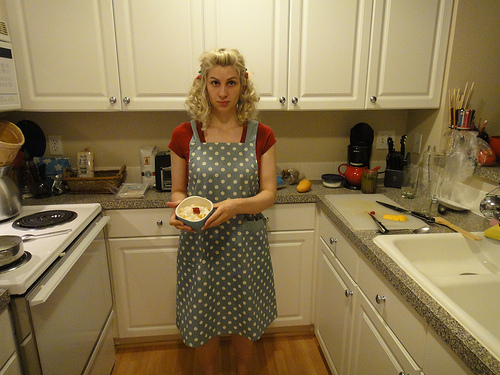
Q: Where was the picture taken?
A: It was taken at the kitchen.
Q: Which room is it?
A: It is a kitchen.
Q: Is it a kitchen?
A: Yes, it is a kitchen.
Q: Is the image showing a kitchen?
A: Yes, it is showing a kitchen.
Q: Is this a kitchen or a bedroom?
A: It is a kitchen.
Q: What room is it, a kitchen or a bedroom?
A: It is a kitchen.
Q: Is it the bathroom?
A: No, it is the kitchen.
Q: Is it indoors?
A: Yes, it is indoors.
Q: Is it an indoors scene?
A: Yes, it is indoors.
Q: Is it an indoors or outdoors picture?
A: It is indoors.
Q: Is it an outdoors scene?
A: No, it is indoors.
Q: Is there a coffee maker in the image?
A: Yes, there is a coffee maker.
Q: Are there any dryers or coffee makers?
A: Yes, there is a coffee maker.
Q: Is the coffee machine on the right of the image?
A: Yes, the coffee machine is on the right of the image.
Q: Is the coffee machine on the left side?
A: No, the coffee machine is on the right of the image.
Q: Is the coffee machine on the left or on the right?
A: The coffee machine is on the right of the image.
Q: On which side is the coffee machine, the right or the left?
A: The coffee machine is on the right of the image.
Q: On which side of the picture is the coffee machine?
A: The coffee machine is on the right of the image.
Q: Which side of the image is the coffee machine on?
A: The coffee machine is on the right of the image.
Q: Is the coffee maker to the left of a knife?
A: Yes, the coffee maker is to the left of a knife.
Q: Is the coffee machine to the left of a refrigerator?
A: No, the coffee machine is to the left of a knife.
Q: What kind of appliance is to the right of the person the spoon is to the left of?
A: The appliance is a coffee maker.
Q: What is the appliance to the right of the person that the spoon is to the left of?
A: The appliance is a coffee maker.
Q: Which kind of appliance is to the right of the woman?
A: The appliance is a coffee maker.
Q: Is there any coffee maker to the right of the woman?
A: Yes, there is a coffee maker to the right of the woman.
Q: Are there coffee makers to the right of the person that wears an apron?
A: Yes, there is a coffee maker to the right of the woman.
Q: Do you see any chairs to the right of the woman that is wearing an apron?
A: No, there is a coffee maker to the right of the woman.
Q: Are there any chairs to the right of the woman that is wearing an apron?
A: No, there is a coffee maker to the right of the woman.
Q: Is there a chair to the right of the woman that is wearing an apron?
A: No, there is a coffee maker to the right of the woman.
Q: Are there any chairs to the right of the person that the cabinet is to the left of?
A: No, there is a coffee maker to the right of the woman.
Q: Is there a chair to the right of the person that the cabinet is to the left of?
A: No, there is a coffee maker to the right of the woman.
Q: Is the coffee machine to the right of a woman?
A: Yes, the coffee machine is to the right of a woman.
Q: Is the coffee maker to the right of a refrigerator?
A: No, the coffee maker is to the right of a woman.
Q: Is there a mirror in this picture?
A: No, there are no mirrors.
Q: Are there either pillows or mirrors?
A: No, there are no mirrors or pillows.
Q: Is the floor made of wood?
A: Yes, the floor is made of wood.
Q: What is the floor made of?
A: The floor is made of wood.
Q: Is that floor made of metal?
A: No, the floor is made of wood.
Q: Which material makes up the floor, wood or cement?
A: The floor is made of wood.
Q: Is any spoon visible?
A: Yes, there is a spoon.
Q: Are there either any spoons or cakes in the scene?
A: Yes, there is a spoon.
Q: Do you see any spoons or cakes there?
A: Yes, there is a spoon.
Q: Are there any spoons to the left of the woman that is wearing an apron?
A: Yes, there is a spoon to the left of the woman.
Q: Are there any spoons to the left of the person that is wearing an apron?
A: Yes, there is a spoon to the left of the woman.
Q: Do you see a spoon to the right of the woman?
A: No, the spoon is to the left of the woman.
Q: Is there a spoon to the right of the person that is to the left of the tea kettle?
A: No, the spoon is to the left of the woman.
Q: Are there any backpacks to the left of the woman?
A: No, there is a spoon to the left of the woman.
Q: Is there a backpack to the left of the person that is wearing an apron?
A: No, there is a spoon to the left of the woman.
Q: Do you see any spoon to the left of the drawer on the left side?
A: Yes, there is a spoon to the left of the drawer.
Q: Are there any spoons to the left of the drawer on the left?
A: Yes, there is a spoon to the left of the drawer.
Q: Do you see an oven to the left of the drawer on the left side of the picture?
A: No, there is a spoon to the left of the drawer.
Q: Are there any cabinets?
A: Yes, there is a cabinet.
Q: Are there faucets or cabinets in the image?
A: Yes, there is a cabinet.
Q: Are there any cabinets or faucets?
A: Yes, there is a cabinet.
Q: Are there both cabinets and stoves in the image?
A: Yes, there are both a cabinet and a stove.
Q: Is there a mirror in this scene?
A: No, there are no mirrors.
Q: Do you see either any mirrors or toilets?
A: No, there are no mirrors or toilets.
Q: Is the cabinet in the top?
A: Yes, the cabinet is in the top of the image.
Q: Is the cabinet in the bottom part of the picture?
A: No, the cabinet is in the top of the image.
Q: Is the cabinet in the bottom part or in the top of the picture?
A: The cabinet is in the top of the image.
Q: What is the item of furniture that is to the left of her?
A: The piece of furniture is a cabinet.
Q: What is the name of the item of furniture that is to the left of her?
A: The piece of furniture is a cabinet.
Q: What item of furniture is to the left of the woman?
A: The piece of furniture is a cabinet.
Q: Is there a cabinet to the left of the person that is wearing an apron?
A: Yes, there is a cabinet to the left of the woman.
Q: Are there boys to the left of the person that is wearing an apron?
A: No, there is a cabinet to the left of the woman.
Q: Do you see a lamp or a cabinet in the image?
A: Yes, there is a cabinet.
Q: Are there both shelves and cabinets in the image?
A: No, there is a cabinet but no shelves.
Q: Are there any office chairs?
A: No, there are no office chairs.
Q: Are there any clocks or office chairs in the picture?
A: No, there are no office chairs or clocks.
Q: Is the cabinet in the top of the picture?
A: Yes, the cabinet is in the top of the image.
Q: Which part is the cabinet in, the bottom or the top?
A: The cabinet is in the top of the image.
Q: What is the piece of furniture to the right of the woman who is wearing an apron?
A: The piece of furniture is a cabinet.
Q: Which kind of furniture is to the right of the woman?
A: The piece of furniture is a cabinet.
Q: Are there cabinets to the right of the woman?
A: Yes, there is a cabinet to the right of the woman.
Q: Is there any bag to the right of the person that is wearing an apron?
A: No, there is a cabinet to the right of the woman.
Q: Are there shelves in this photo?
A: No, there are no shelves.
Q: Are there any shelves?
A: No, there are no shelves.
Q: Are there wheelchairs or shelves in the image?
A: No, there are no shelves or wheelchairs.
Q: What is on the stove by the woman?
A: The stove top is on the stove.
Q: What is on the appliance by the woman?
A: The stove top is on the stove.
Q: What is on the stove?
A: The stove top is on the stove.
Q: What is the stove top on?
A: The stove top is on the stove.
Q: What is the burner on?
A: The stove top is on the stove.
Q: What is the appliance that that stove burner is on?
A: The appliance is a stove.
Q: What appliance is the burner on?
A: The stove burner is on the stove.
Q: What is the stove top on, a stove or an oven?
A: The stove top is on a stove.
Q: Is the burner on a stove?
A: Yes, the burner is on a stove.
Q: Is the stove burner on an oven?
A: No, the stove burner is on a stove.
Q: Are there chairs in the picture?
A: No, there are no chairs.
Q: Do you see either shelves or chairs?
A: No, there are no chairs or shelves.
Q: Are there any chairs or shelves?
A: No, there are no chairs or shelves.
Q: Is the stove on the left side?
A: Yes, the stove is on the left of the image.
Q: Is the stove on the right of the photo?
A: No, the stove is on the left of the image.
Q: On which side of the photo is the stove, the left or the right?
A: The stove is on the left of the image.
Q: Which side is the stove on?
A: The stove is on the left of the image.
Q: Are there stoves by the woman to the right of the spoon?
A: Yes, there is a stove by the woman.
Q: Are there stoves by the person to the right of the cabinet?
A: Yes, there is a stove by the woman.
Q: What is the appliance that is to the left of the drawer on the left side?
A: The appliance is a stove.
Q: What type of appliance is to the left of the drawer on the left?
A: The appliance is a stove.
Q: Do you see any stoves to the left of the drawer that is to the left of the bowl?
A: Yes, there is a stove to the left of the drawer.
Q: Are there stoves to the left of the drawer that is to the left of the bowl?
A: Yes, there is a stove to the left of the drawer.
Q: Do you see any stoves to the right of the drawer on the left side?
A: No, the stove is to the left of the drawer.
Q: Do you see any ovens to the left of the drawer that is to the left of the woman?
A: No, there is a stove to the left of the drawer.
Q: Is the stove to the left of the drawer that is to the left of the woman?
A: Yes, the stove is to the left of the drawer.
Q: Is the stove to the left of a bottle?
A: No, the stove is to the left of the drawer.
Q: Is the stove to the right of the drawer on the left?
A: No, the stove is to the left of the drawer.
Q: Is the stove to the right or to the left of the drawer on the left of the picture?
A: The stove is to the left of the drawer.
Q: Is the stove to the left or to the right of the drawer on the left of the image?
A: The stove is to the left of the drawer.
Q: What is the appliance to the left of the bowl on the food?
A: The appliance is a stove.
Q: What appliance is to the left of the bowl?
A: The appliance is a stove.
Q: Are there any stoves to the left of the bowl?
A: Yes, there is a stove to the left of the bowl.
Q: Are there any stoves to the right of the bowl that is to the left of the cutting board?
A: No, the stove is to the left of the bowl.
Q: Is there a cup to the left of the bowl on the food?
A: No, there is a stove to the left of the bowl.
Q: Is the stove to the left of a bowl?
A: Yes, the stove is to the left of a bowl.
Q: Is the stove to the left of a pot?
A: No, the stove is to the left of a bowl.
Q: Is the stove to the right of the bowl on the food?
A: No, the stove is to the left of the bowl.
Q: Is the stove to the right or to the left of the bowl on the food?
A: The stove is to the left of the bowl.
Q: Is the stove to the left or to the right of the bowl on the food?
A: The stove is to the left of the bowl.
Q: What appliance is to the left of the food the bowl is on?
A: The appliance is a stove.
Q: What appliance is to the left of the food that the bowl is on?
A: The appliance is a stove.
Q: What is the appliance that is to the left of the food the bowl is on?
A: The appliance is a stove.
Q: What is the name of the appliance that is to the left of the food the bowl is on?
A: The appliance is a stove.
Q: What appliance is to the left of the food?
A: The appliance is a stove.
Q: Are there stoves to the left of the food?
A: Yes, there is a stove to the left of the food.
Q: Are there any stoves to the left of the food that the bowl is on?
A: Yes, there is a stove to the left of the food.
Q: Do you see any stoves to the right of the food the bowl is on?
A: No, the stove is to the left of the food.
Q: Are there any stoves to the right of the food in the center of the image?
A: No, the stove is to the left of the food.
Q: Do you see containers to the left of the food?
A: No, there is a stove to the left of the food.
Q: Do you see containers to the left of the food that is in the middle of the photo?
A: No, there is a stove to the left of the food.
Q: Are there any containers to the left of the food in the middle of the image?
A: No, there is a stove to the left of the food.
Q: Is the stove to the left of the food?
A: Yes, the stove is to the left of the food.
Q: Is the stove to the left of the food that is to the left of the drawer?
A: Yes, the stove is to the left of the food.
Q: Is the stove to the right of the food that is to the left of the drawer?
A: No, the stove is to the left of the food.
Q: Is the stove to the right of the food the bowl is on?
A: No, the stove is to the left of the food.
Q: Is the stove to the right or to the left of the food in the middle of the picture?
A: The stove is to the left of the food.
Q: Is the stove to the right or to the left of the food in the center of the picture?
A: The stove is to the left of the food.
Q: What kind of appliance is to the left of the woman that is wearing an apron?
A: The appliance is a stove.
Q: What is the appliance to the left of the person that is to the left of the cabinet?
A: The appliance is a stove.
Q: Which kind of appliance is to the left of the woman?
A: The appliance is a stove.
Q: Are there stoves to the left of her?
A: Yes, there is a stove to the left of the woman.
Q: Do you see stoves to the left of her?
A: Yes, there is a stove to the left of the woman.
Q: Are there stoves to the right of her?
A: No, the stove is to the left of the woman.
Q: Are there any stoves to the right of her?
A: No, the stove is to the left of the woman.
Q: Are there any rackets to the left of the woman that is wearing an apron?
A: No, there is a stove to the left of the woman.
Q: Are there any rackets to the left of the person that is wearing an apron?
A: No, there is a stove to the left of the woman.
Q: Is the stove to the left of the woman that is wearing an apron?
A: Yes, the stove is to the left of the woman.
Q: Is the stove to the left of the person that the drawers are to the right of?
A: Yes, the stove is to the left of the woman.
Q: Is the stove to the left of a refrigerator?
A: No, the stove is to the left of the woman.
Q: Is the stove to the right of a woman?
A: No, the stove is to the left of a woman.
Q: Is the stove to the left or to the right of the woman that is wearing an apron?
A: The stove is to the left of the woman.